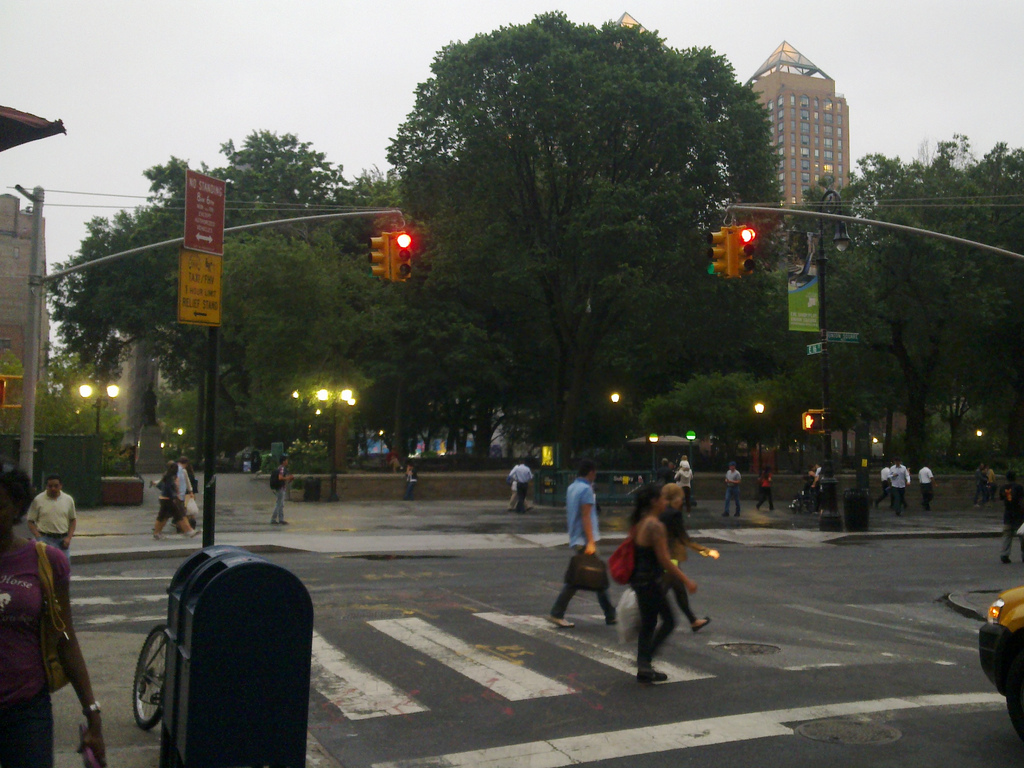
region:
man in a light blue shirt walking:
[541, 454, 619, 633]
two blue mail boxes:
[149, 541, 324, 766]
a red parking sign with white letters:
[179, 162, 231, 260]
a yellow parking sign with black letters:
[171, 241, 230, 334]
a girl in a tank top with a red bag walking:
[604, 480, 690, 690]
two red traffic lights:
[350, 211, 768, 300]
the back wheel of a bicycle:
[128, 623, 177, 734]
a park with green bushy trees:
[82, 111, 1015, 467]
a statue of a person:
[123, 375, 182, 484]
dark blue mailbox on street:
[178, 557, 319, 763]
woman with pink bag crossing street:
[606, 485, 692, 681]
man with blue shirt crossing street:
[554, 464, 619, 629]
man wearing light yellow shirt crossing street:
[25, 474, 77, 573]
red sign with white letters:
[178, 164, 229, 259]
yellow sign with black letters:
[173, 249, 228, 329]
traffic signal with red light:
[368, 219, 419, 286]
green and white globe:
[684, 427, 697, 447]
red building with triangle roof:
[735, 36, 853, 208]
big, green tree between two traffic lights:
[385, 13, 784, 466]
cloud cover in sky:
[0, 3, 1021, 365]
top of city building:
[749, 37, 851, 211]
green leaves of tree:
[392, 13, 782, 451]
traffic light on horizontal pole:
[699, 199, 1022, 282]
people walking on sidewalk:
[0, 446, 1022, 560]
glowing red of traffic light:
[368, 227, 414, 281]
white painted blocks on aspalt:
[302, 600, 1002, 762]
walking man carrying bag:
[548, 460, 622, 628]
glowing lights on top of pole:
[310, 384, 359, 505]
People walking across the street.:
[473, 459, 755, 672]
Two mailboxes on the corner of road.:
[130, 568, 333, 749]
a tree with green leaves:
[390, 19, 780, 438]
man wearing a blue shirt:
[560, 467, 599, 553]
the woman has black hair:
[626, 487, 665, 525]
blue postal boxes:
[156, 540, 312, 763]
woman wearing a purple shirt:
[0, 477, 81, 711]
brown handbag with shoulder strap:
[33, 535, 78, 691]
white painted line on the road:
[368, 606, 568, 712]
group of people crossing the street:
[510, 459, 761, 685]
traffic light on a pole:
[27, 202, 419, 317]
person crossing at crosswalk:
[609, 487, 704, 691]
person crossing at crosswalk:
[553, 463, 623, 633]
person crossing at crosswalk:
[641, 468, 719, 633]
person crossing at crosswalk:
[19, 475, 77, 557]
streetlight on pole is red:
[365, 227, 416, 285]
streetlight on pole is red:
[704, 219, 760, 277]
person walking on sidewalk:
[2, 461, 111, 765]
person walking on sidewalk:
[146, 453, 199, 540]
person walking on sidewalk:
[504, 453, 538, 511]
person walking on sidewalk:
[268, 463, 294, 528]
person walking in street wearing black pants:
[615, 478, 701, 685]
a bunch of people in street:
[15, 436, 1021, 757]